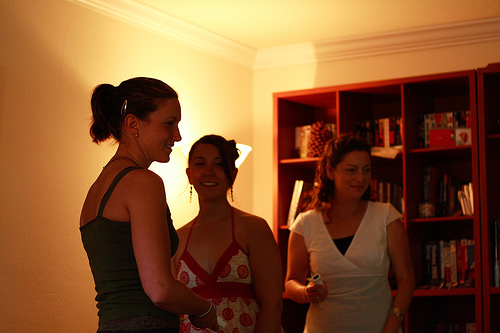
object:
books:
[275, 110, 474, 158]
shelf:
[272, 69, 483, 316]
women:
[77, 77, 415, 333]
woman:
[284, 133, 415, 333]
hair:
[187, 134, 240, 163]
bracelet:
[389, 307, 408, 319]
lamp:
[234, 142, 253, 168]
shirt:
[288, 202, 403, 277]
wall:
[0, 0, 255, 216]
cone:
[306, 120, 333, 158]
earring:
[231, 186, 235, 203]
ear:
[231, 167, 238, 182]